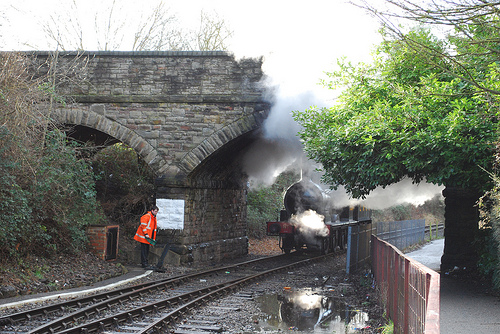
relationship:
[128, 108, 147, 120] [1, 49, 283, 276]
brick on bridge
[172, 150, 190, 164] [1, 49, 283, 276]
grey brick on bridge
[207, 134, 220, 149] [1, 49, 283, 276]
brick on bridge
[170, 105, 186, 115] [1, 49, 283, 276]
brick on bridge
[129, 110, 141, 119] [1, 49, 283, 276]
brick on bridge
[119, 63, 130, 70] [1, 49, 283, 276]
brick on bridge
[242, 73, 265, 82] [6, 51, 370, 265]
brick on bridge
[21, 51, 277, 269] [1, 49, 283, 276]
grey brick on bridge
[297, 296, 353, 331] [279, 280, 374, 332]
reflection in water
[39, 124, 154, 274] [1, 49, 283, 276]
archway under bridge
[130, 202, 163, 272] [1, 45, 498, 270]
man standing under bridge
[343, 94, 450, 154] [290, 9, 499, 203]
green leaves on tree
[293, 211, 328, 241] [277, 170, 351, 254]
steam from train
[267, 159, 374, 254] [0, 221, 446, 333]
train on train tracks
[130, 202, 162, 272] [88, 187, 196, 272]
man wearing jacket